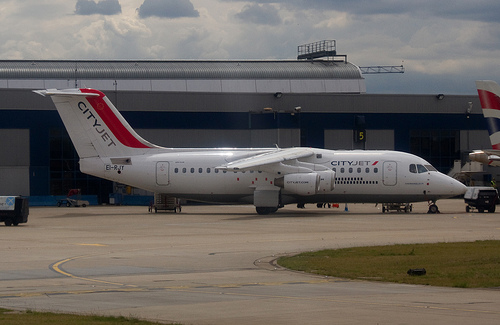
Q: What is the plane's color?
A: White.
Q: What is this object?
A: Plane.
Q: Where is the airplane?
A: At an airport.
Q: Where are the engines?
A: Below the wing.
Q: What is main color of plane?
A: White.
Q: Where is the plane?
A: Airport.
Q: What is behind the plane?
A: A building.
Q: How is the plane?
A: Parked.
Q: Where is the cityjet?
A: On plane.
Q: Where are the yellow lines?
A: On ground.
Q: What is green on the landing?
A: Grass.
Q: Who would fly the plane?
A: Pilot.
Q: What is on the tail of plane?
A: Cityjet.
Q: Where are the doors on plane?
A: Right side.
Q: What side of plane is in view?
A: Right side.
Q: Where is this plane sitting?
A: On the tarmac.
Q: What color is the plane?
A: White and red.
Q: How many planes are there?
A: 2.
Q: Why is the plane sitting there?
A: Waiting to load or unload.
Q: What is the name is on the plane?
A: Cityjet.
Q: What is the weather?
A: Overcast.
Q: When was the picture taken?
A: During the day.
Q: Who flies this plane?
A: A pilot.